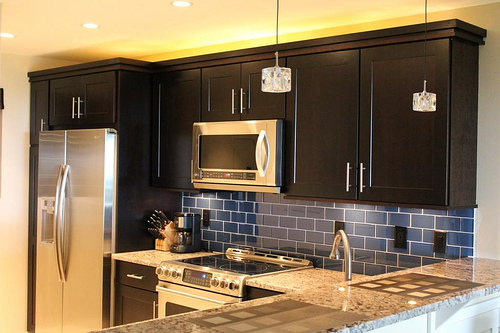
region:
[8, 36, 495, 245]
the cabinets are black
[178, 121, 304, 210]
the microwave is silver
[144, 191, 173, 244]
knives in brown holder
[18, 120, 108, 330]
refridgerator built in cabinets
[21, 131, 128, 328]
the fridge is silver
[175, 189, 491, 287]
wall made of brick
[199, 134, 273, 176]
window of microwave is black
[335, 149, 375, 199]
silver handles on cabinets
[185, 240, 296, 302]
stove has flat stove top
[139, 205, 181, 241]
the knives are black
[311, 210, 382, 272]
silver faucet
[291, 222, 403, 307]
silver faucet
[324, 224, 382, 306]
silver faucet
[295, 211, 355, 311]
silver faucet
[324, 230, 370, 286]
a kitchen faucet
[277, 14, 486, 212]
black cupboards in a kitchen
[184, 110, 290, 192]
a silver colored microwave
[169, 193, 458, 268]
a tile backsplash behind a stove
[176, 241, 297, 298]
a flat stove top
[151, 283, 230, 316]
an oven door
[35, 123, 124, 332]
a double doored refrigerator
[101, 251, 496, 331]
a speckled counter top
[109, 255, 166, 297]
a black drawer under a counter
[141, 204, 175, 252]
knives in a knife holder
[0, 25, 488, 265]
large kitchen room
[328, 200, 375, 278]
silver kitchen faucet sticking up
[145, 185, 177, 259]
knife holder filled with knives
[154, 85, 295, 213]
built in silver microwave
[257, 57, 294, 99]
box lights hanging down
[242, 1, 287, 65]
black cords for lights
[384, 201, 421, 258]
black wall outlets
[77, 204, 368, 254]
blue and white wall tile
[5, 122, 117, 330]
two door fridge and freezer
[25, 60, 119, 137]
black cabinets above fridge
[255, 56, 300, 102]
cube shaped hanging light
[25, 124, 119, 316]
doors on stainless steel fridge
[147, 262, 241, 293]
knobs on front of stove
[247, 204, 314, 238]
blue tile backsplash on wall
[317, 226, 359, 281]
curved metal kitchen faucet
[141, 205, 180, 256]
knives in wood block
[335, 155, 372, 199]
handles on kitchen cupboards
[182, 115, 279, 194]
microwave under kitchen cabinets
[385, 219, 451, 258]
black outlets on wall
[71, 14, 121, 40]
recessed light in ceiling